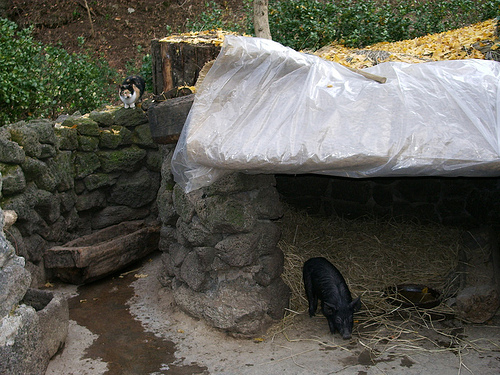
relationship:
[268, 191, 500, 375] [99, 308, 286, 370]
hay on ground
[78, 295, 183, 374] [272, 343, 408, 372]
water on floor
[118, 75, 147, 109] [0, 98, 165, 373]
black cat on wall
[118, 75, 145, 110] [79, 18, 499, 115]
dog in mulch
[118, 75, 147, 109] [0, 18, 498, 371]
black cat standing wall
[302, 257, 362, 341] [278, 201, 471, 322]
boar standing on hay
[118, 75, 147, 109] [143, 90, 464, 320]
black cat overlooking home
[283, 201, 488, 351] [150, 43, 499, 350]
hay under cave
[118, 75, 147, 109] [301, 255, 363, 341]
black cat watching pig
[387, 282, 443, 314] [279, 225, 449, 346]
water bowl in hay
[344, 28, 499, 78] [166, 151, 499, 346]
leaves above cave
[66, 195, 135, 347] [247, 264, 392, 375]
food trough for a pig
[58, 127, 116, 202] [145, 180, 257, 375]
rock wall and trough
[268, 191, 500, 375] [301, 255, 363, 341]
hay for pig